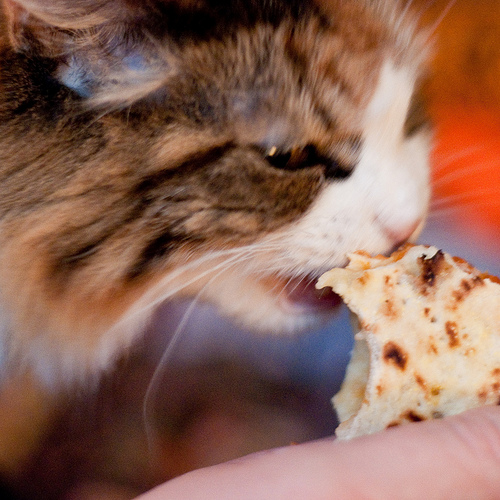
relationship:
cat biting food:
[1, 0, 434, 397] [315, 240, 499, 441]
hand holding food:
[128, 403, 499, 500] [315, 240, 499, 441]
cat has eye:
[1, 0, 434, 397] [249, 140, 322, 173]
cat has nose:
[1, 0, 434, 397] [376, 217, 424, 246]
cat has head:
[1, 0, 434, 397] [88, 1, 434, 335]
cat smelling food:
[1, 0, 434, 397] [315, 240, 499, 441]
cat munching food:
[1, 0, 434, 397] [315, 240, 499, 441]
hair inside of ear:
[16, 0, 121, 31] [4, 1, 166, 56]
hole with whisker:
[327, 214, 338, 223] [100, 216, 339, 339]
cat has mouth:
[1, 0, 434, 397] [263, 256, 392, 316]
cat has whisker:
[1, 0, 434, 397] [141, 252, 265, 463]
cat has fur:
[1, 0, 434, 397] [2, 0, 434, 382]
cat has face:
[1, 0, 434, 397] [222, 21, 434, 328]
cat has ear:
[1, 0, 434, 397] [4, 1, 166, 56]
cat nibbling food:
[1, 0, 434, 397] [315, 240, 499, 441]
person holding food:
[131, 406, 499, 499] [315, 240, 499, 441]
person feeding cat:
[131, 406, 499, 499] [1, 0, 434, 397]